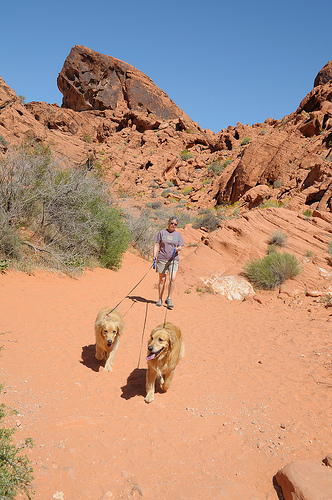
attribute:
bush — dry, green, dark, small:
[240, 246, 304, 288]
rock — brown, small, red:
[272, 456, 331, 498]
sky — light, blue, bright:
[2, 1, 332, 128]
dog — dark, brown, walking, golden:
[142, 321, 187, 405]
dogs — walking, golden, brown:
[90, 303, 188, 404]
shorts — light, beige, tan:
[155, 257, 178, 277]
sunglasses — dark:
[168, 221, 180, 229]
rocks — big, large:
[2, 37, 331, 306]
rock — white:
[209, 272, 256, 302]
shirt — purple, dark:
[155, 225, 186, 263]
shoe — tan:
[157, 296, 173, 309]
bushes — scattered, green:
[0, 128, 312, 289]